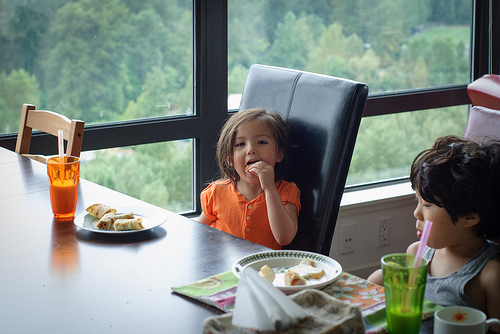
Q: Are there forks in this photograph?
A: No, there are no forks.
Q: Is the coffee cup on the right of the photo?
A: Yes, the coffee cup is on the right of the image.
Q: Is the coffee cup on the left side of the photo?
A: No, the coffee cup is on the right of the image.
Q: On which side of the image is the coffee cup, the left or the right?
A: The coffee cup is on the right of the image.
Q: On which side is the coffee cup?
A: The coffee cup is on the right of the image.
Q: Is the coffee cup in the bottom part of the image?
A: Yes, the coffee cup is in the bottom of the image.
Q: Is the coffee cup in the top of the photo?
A: No, the coffee cup is in the bottom of the image.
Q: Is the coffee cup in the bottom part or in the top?
A: The coffee cup is in the bottom of the image.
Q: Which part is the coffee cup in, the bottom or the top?
A: The coffee cup is in the bottom of the image.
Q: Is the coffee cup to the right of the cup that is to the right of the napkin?
A: Yes, the coffee cup is to the right of the cup.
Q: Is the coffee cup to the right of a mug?
A: No, the coffee cup is to the right of the cup.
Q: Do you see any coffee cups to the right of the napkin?
A: Yes, there is a coffee cup to the right of the napkin.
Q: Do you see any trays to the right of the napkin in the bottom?
A: No, there is a coffee cup to the right of the napkin.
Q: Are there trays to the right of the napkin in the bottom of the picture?
A: No, there is a coffee cup to the right of the napkin.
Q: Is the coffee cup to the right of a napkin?
A: Yes, the coffee cup is to the right of a napkin.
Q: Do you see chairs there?
A: Yes, there is a chair.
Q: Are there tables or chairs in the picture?
A: Yes, there is a chair.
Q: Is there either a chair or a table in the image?
A: Yes, there is a chair.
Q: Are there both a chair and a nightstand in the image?
A: No, there is a chair but no nightstands.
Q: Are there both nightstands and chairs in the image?
A: No, there is a chair but no nightstands.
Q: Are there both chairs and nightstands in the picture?
A: No, there is a chair but no nightstands.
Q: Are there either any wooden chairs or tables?
A: Yes, there is a wood chair.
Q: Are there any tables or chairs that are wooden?
A: Yes, the chair is wooden.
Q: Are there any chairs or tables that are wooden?
A: Yes, the chair is wooden.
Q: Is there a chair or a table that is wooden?
A: Yes, the chair is wooden.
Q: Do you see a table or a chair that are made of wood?
A: Yes, the chair is made of wood.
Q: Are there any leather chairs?
A: Yes, there is a chair that is made of leather.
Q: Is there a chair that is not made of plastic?
A: Yes, there is a chair that is made of leather.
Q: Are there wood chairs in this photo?
A: Yes, there is a wood chair.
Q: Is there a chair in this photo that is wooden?
A: Yes, there is a chair that is wooden.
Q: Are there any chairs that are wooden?
A: Yes, there is a chair that is wooden.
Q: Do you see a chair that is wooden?
A: Yes, there is a chair that is wooden.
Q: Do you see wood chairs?
A: Yes, there is a chair that is made of wood.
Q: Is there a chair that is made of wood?
A: Yes, there is a chair that is made of wood.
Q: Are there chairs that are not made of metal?
A: Yes, there is a chair that is made of wood.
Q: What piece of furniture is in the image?
A: The piece of furniture is a chair.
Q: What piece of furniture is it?
A: The piece of furniture is a chair.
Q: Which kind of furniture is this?
A: This is a chair.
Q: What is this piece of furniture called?
A: This is a chair.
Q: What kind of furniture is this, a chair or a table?
A: This is a chair.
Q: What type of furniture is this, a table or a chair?
A: This is a chair.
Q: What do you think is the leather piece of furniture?
A: The piece of furniture is a chair.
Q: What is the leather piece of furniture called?
A: The piece of furniture is a chair.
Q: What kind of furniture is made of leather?
A: The furniture is a chair.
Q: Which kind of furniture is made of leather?
A: The furniture is a chair.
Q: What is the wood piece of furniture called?
A: The piece of furniture is a chair.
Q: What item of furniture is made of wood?
A: The piece of furniture is a chair.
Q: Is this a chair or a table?
A: This is a chair.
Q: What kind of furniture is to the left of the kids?
A: The piece of furniture is a chair.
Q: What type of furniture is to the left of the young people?
A: The piece of furniture is a chair.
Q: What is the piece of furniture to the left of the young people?
A: The piece of furniture is a chair.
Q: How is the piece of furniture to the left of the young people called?
A: The piece of furniture is a chair.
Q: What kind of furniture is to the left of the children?
A: The piece of furniture is a chair.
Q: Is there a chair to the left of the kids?
A: Yes, there is a chair to the left of the kids.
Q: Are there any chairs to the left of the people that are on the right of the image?
A: Yes, there is a chair to the left of the kids.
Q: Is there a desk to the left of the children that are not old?
A: No, there is a chair to the left of the children.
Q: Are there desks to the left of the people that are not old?
A: No, there is a chair to the left of the children.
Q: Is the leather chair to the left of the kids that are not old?
A: Yes, the chair is to the left of the children.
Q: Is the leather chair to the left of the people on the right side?
A: Yes, the chair is to the left of the children.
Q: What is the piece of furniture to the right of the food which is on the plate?
A: The piece of furniture is a chair.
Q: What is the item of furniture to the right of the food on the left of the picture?
A: The piece of furniture is a chair.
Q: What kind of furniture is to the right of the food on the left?
A: The piece of furniture is a chair.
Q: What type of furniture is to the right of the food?
A: The piece of furniture is a chair.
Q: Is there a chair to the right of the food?
A: Yes, there is a chair to the right of the food.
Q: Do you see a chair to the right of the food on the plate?
A: Yes, there is a chair to the right of the food.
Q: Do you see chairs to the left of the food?
A: No, the chair is to the right of the food.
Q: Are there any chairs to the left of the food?
A: No, the chair is to the right of the food.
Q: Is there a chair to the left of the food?
A: No, the chair is to the right of the food.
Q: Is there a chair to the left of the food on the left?
A: No, the chair is to the right of the food.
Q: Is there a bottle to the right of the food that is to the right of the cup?
A: No, there is a chair to the right of the food.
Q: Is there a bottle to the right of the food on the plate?
A: No, there is a chair to the right of the food.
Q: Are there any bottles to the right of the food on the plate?
A: No, there is a chair to the right of the food.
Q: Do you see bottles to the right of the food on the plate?
A: No, there is a chair to the right of the food.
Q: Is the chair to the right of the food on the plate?
A: Yes, the chair is to the right of the food.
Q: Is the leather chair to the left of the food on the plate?
A: No, the chair is to the right of the food.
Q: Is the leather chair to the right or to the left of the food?
A: The chair is to the right of the food.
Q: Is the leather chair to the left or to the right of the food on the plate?
A: The chair is to the right of the food.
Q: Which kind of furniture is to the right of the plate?
A: The piece of furniture is a chair.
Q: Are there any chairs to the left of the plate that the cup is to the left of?
A: No, the chair is to the right of the plate.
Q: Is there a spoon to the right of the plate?
A: No, there is a chair to the right of the plate.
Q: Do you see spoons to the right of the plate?
A: No, there is a chair to the right of the plate.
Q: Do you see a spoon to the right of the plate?
A: No, there is a chair to the right of the plate.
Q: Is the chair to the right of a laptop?
A: No, the chair is to the right of the plate.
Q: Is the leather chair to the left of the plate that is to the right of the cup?
A: No, the chair is to the right of the plate.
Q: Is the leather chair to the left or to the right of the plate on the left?
A: The chair is to the right of the plate.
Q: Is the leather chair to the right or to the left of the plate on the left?
A: The chair is to the right of the plate.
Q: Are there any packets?
A: No, there are no packets.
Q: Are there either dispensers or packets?
A: No, there are no packets or dispensers.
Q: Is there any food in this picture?
A: Yes, there is food.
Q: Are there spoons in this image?
A: No, there are no spoons.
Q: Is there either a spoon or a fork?
A: No, there are no spoons or forks.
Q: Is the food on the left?
A: Yes, the food is on the left of the image.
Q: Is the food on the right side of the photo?
A: No, the food is on the left of the image.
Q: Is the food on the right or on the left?
A: The food is on the left of the image.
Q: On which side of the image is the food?
A: The food is on the left of the image.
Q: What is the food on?
A: The food is on the plate.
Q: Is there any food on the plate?
A: Yes, there is food on the plate.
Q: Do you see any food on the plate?
A: Yes, there is food on the plate.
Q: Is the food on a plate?
A: Yes, the food is on a plate.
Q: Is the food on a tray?
A: No, the food is on a plate.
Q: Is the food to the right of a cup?
A: Yes, the food is to the right of a cup.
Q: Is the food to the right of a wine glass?
A: No, the food is to the right of a cup.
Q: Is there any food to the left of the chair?
A: Yes, there is food to the left of the chair.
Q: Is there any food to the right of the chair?
A: No, the food is to the left of the chair.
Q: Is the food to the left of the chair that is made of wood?
A: Yes, the food is to the left of the chair.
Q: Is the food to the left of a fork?
A: No, the food is to the left of the chair.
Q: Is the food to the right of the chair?
A: No, the food is to the left of the chair.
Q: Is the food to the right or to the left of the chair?
A: The food is to the left of the chair.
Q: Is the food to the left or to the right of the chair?
A: The food is to the left of the chair.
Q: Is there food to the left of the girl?
A: Yes, there is food to the left of the girl.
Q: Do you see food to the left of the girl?
A: Yes, there is food to the left of the girl.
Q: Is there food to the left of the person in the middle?
A: Yes, there is food to the left of the girl.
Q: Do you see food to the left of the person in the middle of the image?
A: Yes, there is food to the left of the girl.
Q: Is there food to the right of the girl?
A: No, the food is to the left of the girl.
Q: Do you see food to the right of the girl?
A: No, the food is to the left of the girl.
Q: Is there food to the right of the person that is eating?
A: No, the food is to the left of the girl.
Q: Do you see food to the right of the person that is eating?
A: No, the food is to the left of the girl.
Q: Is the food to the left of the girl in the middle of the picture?
A: Yes, the food is to the left of the girl.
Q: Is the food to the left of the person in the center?
A: Yes, the food is to the left of the girl.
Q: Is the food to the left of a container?
A: No, the food is to the left of the girl.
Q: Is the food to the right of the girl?
A: No, the food is to the left of the girl.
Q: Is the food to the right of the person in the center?
A: No, the food is to the left of the girl.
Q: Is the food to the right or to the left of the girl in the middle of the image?
A: The food is to the left of the girl.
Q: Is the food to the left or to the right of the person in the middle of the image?
A: The food is to the left of the girl.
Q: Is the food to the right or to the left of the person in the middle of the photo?
A: The food is to the left of the girl.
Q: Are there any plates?
A: Yes, there is a plate.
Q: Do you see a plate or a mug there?
A: Yes, there is a plate.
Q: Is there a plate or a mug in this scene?
A: Yes, there is a plate.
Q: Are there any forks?
A: No, there are no forks.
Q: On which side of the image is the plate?
A: The plate is on the left of the image.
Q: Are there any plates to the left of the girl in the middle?
A: Yes, there is a plate to the left of the girl.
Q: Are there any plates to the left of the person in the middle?
A: Yes, there is a plate to the left of the girl.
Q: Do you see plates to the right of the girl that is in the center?
A: No, the plate is to the left of the girl.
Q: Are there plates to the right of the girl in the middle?
A: No, the plate is to the left of the girl.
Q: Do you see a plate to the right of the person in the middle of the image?
A: No, the plate is to the left of the girl.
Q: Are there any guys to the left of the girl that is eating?
A: No, there is a plate to the left of the girl.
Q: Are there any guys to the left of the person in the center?
A: No, there is a plate to the left of the girl.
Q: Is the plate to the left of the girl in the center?
A: Yes, the plate is to the left of the girl.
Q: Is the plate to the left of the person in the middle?
A: Yes, the plate is to the left of the girl.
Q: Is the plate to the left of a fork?
A: No, the plate is to the left of the girl.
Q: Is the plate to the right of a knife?
A: No, the plate is to the right of the cup.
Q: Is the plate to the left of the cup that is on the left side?
A: No, the plate is to the right of the cup.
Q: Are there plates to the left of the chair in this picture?
A: Yes, there is a plate to the left of the chair.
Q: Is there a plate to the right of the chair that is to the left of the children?
A: No, the plate is to the left of the chair.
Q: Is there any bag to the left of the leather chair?
A: No, there is a plate to the left of the chair.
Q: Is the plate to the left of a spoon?
A: No, the plate is to the left of a chair.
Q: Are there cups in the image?
A: Yes, there is a cup.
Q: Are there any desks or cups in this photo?
A: Yes, there is a cup.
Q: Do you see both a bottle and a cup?
A: No, there is a cup but no bottles.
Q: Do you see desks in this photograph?
A: No, there are no desks.